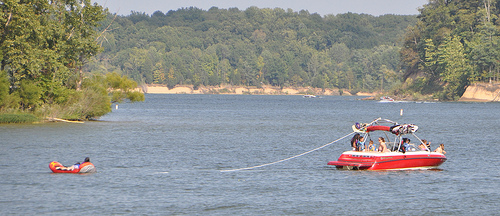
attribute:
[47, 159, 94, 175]
float — red, white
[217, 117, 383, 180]
rope — in the picture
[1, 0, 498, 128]
forest — in the picture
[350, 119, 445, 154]
people — in the picture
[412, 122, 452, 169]
ground — in the picture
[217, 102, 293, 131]
water — in the picture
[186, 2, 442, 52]
clouds — in the picture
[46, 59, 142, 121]
bush — green, big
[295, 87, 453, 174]
float — red, white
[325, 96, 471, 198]
boat — in the picture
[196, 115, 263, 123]
water — in the picture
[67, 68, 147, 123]
bush — big, green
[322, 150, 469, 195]
boat — in the picture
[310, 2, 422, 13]
sky — in the picture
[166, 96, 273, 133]
river — in the picture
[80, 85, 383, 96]
dry terrain — in the picture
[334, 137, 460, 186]
float — white, red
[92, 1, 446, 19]
sky — blue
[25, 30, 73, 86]
leaves — green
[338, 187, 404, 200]
water — in the picture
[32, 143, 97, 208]
float — white, red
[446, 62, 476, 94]
bush — big, green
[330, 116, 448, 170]
boat — in the picture